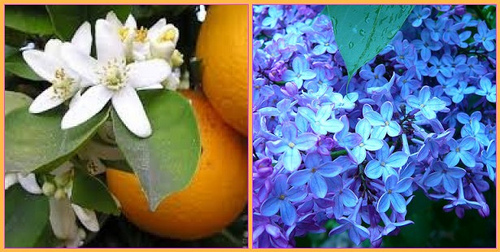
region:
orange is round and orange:
[78, 88, 264, 248]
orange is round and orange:
[165, 0, 311, 197]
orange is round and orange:
[164, 4, 294, 84]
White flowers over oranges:
[18, 5, 194, 142]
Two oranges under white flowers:
[97, 2, 253, 232]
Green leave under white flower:
[102, 82, 207, 213]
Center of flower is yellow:
[91, 52, 137, 92]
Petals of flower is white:
[59, 85, 152, 140]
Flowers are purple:
[253, 0, 498, 247]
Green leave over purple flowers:
[328, 7, 418, 78]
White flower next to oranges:
[9, 164, 120, 241]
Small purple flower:
[356, 100, 401, 142]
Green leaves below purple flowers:
[412, 206, 492, 246]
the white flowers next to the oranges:
[23, 8, 180, 141]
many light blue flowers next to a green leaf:
[255, 3, 498, 246]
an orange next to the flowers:
[194, 8, 249, 136]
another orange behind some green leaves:
[101, 99, 245, 236]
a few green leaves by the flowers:
[10, 89, 199, 208]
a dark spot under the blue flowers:
[411, 206, 498, 241]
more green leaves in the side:
[3, 3, 76, 250]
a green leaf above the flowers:
[328, 7, 413, 75]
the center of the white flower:
[96, 57, 125, 91]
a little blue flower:
[288, 148, 335, 194]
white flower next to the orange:
[45, 20, 176, 143]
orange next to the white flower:
[104, 76, 248, 241]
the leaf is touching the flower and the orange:
[104, 81, 212, 203]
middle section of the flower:
[94, 58, 141, 101]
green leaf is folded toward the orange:
[65, 161, 137, 231]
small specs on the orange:
[182, 106, 229, 172]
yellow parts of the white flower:
[111, 26, 157, 42]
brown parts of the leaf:
[66, 198, 127, 221]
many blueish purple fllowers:
[259, 11, 423, 243]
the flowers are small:
[269, 41, 370, 178]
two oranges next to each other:
[111, 7, 246, 239]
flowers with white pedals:
[67, 34, 157, 137]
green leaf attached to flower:
[114, 91, 199, 220]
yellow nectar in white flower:
[153, 20, 179, 52]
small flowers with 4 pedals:
[290, 106, 379, 195]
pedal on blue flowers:
[377, 99, 398, 121]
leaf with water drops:
[346, 7, 401, 59]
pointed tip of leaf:
[134, 178, 189, 230]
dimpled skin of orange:
[217, 30, 244, 88]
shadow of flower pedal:
[39, 103, 65, 130]